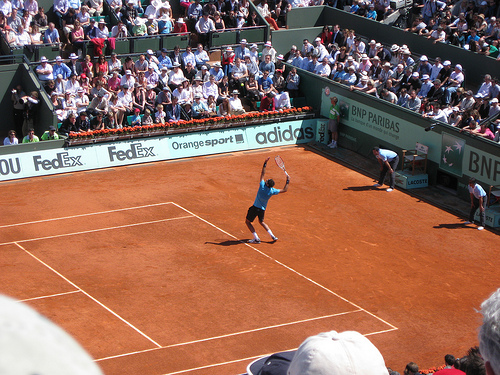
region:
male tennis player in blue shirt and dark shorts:
[243, 156, 289, 242]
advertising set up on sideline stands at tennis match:
[0, 119, 317, 180]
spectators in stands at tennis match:
[0, 1, 499, 147]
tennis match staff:
[323, 97, 499, 231]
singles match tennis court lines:
[3, 215, 398, 358]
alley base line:
[362, 309, 395, 328]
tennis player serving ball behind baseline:
[241, 144, 291, 254]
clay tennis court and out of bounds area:
[3, 141, 498, 373]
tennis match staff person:
[323, 95, 340, 147]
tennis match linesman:
[371, 141, 432, 193]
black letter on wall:
[1, 157, 10, 175]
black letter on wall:
[9, 153, 21, 175]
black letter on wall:
[32, 150, 42, 169]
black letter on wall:
[41, 156, 53, 171]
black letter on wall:
[51, 150, 63, 170]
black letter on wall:
[107, 141, 119, 161]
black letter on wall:
[117, 148, 127, 160]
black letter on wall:
[127, 141, 136, 161]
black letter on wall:
[256, 128, 268, 144]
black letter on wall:
[266, 125, 279, 143]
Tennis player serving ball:
[239, 153, 293, 245]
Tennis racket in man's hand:
[275, 153, 287, 179]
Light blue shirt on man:
[254, 180, 280, 209]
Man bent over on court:
[370, 144, 395, 189]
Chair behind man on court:
[402, 143, 429, 170]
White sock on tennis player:
[252, 233, 260, 244]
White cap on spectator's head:
[295, 330, 397, 373]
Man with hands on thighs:
[463, 178, 490, 233]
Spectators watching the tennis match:
[37, 51, 332, 124]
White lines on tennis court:
[7, 199, 402, 369]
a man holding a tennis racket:
[233, 147, 305, 252]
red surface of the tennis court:
[341, 225, 413, 286]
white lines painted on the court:
[62, 178, 192, 255]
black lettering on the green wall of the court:
[83, 129, 253, 170]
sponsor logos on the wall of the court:
[101, 119, 326, 169]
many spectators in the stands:
[66, 50, 283, 126]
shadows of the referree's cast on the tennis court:
[339, 181, 464, 248]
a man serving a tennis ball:
[232, 145, 299, 252]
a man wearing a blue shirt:
[243, 157, 300, 252]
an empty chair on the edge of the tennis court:
[400, 139, 437, 195]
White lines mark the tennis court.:
[0, 200, 397, 372]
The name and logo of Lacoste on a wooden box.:
[392, 175, 430, 189]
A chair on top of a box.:
[394, 142, 429, 189]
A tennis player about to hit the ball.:
[233, 155, 289, 242]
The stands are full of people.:
[0, 2, 498, 146]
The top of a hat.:
[287, 330, 387, 374]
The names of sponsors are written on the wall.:
[0, 117, 327, 181]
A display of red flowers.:
[65, 103, 315, 149]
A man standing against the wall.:
[326, 93, 340, 152]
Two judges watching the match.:
[369, 145, 486, 231]